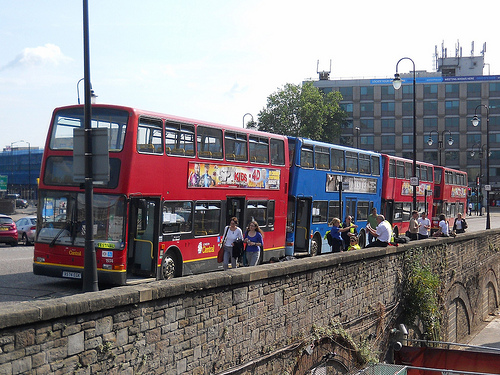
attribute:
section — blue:
[285, 132, 383, 259]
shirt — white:
[415, 217, 434, 232]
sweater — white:
[225, 221, 235, 244]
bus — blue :
[287, 135, 387, 257]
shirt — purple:
[240, 232, 265, 251]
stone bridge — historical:
[1, 227, 498, 372]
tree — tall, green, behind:
[254, 86, 341, 129]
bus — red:
[32, 90, 297, 302]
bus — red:
[59, 135, 249, 255]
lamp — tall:
[393, 56, 418, 211]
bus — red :
[36, 106, 291, 271]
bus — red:
[32, 103, 289, 285]